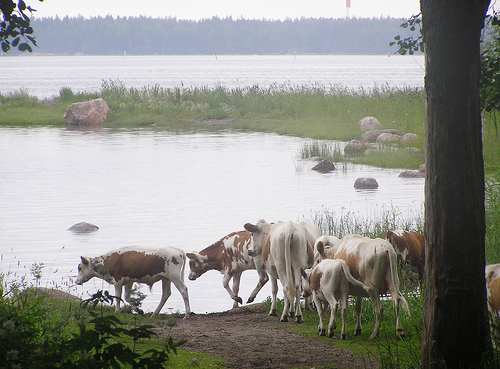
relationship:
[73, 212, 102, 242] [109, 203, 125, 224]
rock in water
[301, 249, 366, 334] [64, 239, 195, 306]
cow bear cow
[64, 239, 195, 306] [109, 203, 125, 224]
cow near water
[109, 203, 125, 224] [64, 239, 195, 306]
water near cow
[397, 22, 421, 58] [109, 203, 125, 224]
tree near water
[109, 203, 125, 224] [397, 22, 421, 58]
water near tree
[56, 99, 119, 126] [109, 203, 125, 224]
rock near water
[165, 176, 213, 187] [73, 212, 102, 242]
water near rock